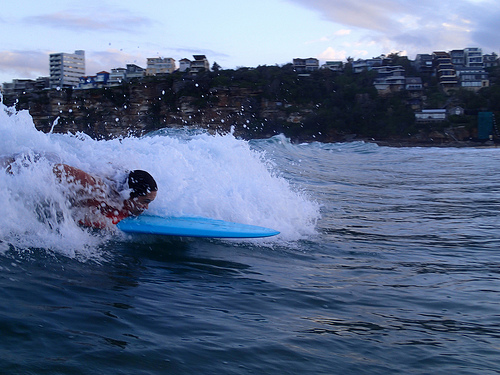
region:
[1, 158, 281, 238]
Surfer laying on their board in the water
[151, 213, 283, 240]
Front end of a surfboard in the water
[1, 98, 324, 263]
Water splashing as a wave crashes down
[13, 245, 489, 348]
Deep blue water of the ocean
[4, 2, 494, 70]
Blue skies with grayish clouds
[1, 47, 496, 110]
Skyline of a distant city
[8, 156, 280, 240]
Surfer on a board, swimming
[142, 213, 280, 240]
A surfboard in the water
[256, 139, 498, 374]
Dark blue water of the ocean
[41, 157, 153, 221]
A surfer surrounded by splashing water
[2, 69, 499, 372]
Body of water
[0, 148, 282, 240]
Person on a surfboard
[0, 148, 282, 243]
Person surfing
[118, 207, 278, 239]
Surfboard in the water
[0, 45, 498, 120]
Row of buildings away from the water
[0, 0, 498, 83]
Cloudy sky outside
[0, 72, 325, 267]
Splash of water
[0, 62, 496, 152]
Shoreline next to the water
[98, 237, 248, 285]
Shadow of the surfboard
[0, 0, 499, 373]
Urban area with an ocean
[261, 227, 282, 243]
tip of blue board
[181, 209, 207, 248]
middle of blue board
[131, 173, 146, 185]
man with black hair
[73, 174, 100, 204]
water splashing on man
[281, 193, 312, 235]
water splashing in ocean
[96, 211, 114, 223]
red paint on board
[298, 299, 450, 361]
small waves in the water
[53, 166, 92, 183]
man arm in water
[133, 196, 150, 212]
man face in water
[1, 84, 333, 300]
man surfing in water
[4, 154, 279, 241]
A person on a surfboard.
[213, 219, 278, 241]
Part of a surfboard.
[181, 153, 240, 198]
Part of a wave.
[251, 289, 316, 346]
Part of the water.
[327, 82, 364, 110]
Trees in the distance.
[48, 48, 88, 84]
A large building in the distance.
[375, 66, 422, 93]
Buildings on a hill.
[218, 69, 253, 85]
Trees in the distance.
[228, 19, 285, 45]
Part of the sky.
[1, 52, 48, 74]
A purple cloud.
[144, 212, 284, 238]
part of blue surfboard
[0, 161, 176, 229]
surfer on surfboard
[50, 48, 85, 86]
tallest residential building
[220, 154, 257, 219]
foam of sea wave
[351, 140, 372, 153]
waves developing in sea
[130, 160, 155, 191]
short black hair on person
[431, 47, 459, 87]
balconies in residential building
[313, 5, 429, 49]
part of cloudy skies.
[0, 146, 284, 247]
man is laying on surfboard .